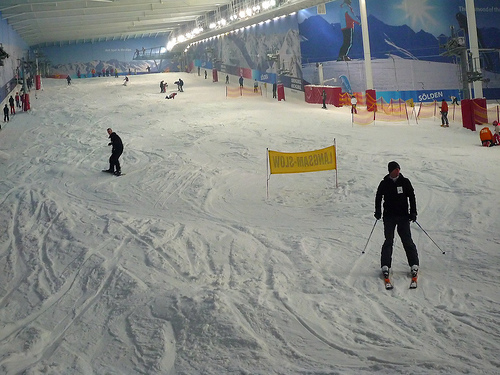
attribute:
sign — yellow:
[258, 142, 355, 182]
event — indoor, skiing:
[5, 5, 495, 373]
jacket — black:
[370, 174, 433, 228]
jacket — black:
[107, 129, 126, 159]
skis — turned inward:
[383, 268, 440, 301]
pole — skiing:
[412, 209, 466, 266]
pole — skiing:
[360, 213, 389, 270]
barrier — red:
[301, 79, 353, 114]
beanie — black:
[383, 155, 416, 182]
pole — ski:
[415, 216, 463, 264]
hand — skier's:
[408, 203, 421, 222]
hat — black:
[381, 155, 412, 177]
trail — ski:
[7, 178, 277, 368]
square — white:
[395, 182, 410, 201]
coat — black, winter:
[370, 174, 421, 224]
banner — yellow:
[265, 142, 352, 194]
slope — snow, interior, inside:
[11, 73, 491, 373]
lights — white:
[156, 0, 316, 54]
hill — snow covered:
[12, 68, 492, 373]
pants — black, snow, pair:
[377, 218, 437, 278]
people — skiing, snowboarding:
[28, 53, 456, 326]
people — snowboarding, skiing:
[23, 60, 480, 372]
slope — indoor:
[25, 85, 359, 365]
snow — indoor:
[29, 180, 339, 362]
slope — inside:
[36, 71, 458, 371]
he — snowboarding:
[92, 120, 148, 182]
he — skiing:
[327, 150, 434, 278]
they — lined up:
[4, 73, 61, 128]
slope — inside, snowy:
[32, 79, 407, 319]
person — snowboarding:
[355, 148, 475, 283]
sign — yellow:
[244, 131, 349, 190]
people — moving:
[5, 55, 36, 135]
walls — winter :
[196, 17, 456, 130]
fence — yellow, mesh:
[270, 71, 477, 146]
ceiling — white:
[24, 5, 189, 46]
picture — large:
[297, 0, 482, 123]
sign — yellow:
[267, 142, 344, 182]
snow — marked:
[40, 186, 294, 354]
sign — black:
[251, 129, 351, 172]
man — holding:
[339, 164, 439, 251]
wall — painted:
[355, 0, 458, 81]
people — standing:
[10, 63, 26, 128]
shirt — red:
[334, 19, 363, 32]